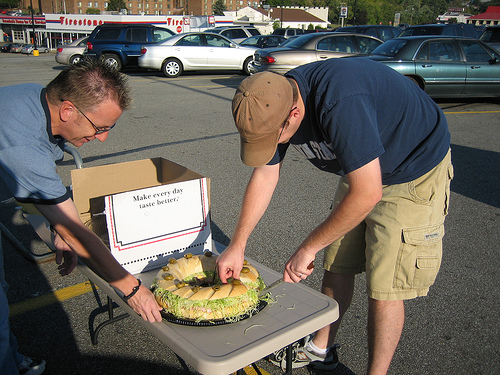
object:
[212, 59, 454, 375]
man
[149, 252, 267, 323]
sandwich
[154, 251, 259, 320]
bread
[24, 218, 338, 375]
table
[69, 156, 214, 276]
box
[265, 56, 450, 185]
t-shirt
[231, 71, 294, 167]
cap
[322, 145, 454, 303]
shorts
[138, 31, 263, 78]
car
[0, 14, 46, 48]
store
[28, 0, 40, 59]
pole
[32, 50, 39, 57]
base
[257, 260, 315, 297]
knife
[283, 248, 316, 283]
hand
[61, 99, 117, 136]
glasses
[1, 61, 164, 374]
man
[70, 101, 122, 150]
face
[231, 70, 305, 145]
head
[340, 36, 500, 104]
vehicle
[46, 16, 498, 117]
parking lot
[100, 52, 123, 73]
rear wheel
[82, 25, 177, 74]
vehicle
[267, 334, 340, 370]
sneakers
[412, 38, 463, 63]
side windows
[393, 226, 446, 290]
pocket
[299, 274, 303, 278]
ring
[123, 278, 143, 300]
bracelet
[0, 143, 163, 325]
arm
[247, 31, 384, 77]
car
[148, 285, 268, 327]
tray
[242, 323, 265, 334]
lettuce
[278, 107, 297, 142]
glasses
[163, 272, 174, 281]
olives